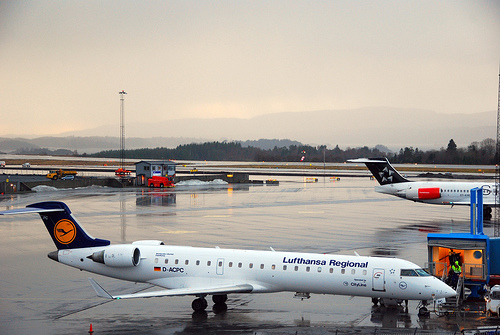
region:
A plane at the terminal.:
[28, 177, 450, 326]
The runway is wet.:
[181, 165, 359, 243]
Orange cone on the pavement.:
[66, 306, 108, 334]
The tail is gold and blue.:
[26, 194, 84, 243]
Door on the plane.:
[361, 259, 388, 293]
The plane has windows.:
[248, 255, 327, 284]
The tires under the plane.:
[178, 294, 234, 311]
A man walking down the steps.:
[450, 258, 464, 283]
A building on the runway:
[126, 141, 181, 187]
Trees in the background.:
[161, 128, 306, 163]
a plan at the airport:
[0, 195, 462, 316]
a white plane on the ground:
[0, 190, 460, 324]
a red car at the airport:
[141, 171, 182, 192]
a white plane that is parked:
[1, 193, 463, 319]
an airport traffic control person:
[443, 255, 468, 280]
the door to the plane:
[368, 264, 388, 297]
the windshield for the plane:
[400, 263, 428, 281]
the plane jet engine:
[86, 247, 148, 269]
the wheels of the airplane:
[187, 296, 213, 313]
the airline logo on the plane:
[43, 214, 79, 246]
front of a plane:
[392, 234, 462, 301]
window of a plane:
[408, 268, 438, 282]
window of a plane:
[358, 267, 369, 274]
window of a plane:
[350, 267, 356, 276]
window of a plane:
[338, 264, 350, 275]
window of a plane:
[328, 262, 337, 279]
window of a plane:
[300, 262, 315, 272]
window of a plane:
[283, 258, 293, 275]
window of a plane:
[245, 260, 257, 270]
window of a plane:
[236, 259, 244, 267]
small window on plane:
[360, 267, 367, 276]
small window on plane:
[348, 266, 356, 274]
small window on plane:
[341, 267, 346, 276]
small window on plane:
[315, 263, 322, 271]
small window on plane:
[303, 264, 310, 273]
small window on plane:
[293, 264, 298, 272]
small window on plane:
[280, 263, 288, 270]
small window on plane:
[269, 263, 276, 270]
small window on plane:
[259, 261, 264, 271]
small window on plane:
[165, 258, 172, 264]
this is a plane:
[28, 185, 468, 317]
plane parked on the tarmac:
[29, 174, 459, 334]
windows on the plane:
[156, 250, 376, 286]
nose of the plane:
[416, 270, 464, 300]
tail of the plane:
[18, 185, 103, 272]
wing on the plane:
[62, 267, 253, 319]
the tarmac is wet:
[88, 173, 374, 249]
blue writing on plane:
[274, 247, 379, 279]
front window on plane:
[389, 265, 433, 282]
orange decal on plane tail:
[45, 217, 87, 248]